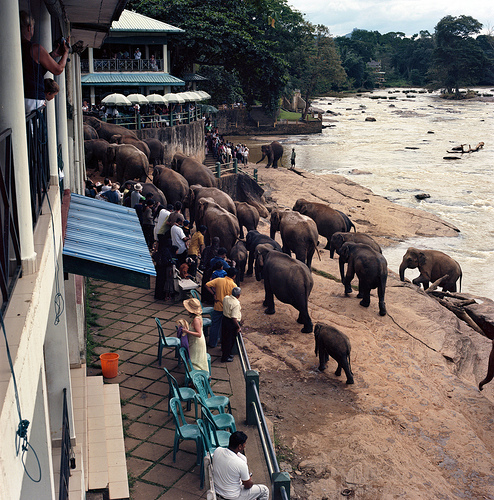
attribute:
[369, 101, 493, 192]
river — rapid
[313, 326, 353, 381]
elephant — baby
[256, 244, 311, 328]
elephant — adult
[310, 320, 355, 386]
elephant — baby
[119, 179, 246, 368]
people — gathered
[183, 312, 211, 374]
dress — long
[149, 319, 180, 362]
chair — green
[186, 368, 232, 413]
chair — green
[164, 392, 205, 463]
chair — green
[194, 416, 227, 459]
chair — green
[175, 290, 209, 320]
hat — straw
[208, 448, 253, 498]
shirt — white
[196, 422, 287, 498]
man — sitting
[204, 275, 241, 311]
shirt — yellow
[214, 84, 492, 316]
water — dark, green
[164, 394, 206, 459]
chair — blue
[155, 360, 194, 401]
chair — blue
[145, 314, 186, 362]
chair — blue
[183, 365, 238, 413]
chair — blue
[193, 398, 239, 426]
chair — blue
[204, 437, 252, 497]
shirt — white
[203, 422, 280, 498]
man — in white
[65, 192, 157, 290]
awning — blue, tin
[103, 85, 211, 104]
umbrellas — white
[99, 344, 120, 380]
bucket — orange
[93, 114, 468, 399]
elephants — Asian, herd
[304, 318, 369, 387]
elephant — small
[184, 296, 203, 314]
hat — tan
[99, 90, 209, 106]
umbrellas — white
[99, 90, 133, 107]
umbrella — white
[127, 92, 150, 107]
umbrella — white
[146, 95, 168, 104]
umbrella — white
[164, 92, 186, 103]
umbrella — white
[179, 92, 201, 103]
umbrella — white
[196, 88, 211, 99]
umbrella — white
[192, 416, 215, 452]
chair — green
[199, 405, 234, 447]
chair — green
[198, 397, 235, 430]
chair — green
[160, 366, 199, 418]
chair — green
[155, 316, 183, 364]
chair — green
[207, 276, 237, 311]
shirt — orange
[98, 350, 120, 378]
bucket — orange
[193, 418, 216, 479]
chair — blue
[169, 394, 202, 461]
chair — blue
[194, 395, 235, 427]
chair — blue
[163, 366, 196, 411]
chair — blue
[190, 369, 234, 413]
chair — blue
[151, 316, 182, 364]
chair — blue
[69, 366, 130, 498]
staircase — white, tiled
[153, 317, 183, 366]
chair — plastic, blue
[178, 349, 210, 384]
chair — plastic, blue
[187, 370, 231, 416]
chair — plastic, blue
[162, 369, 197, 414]
chair — plastic, blue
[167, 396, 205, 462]
chair — plastic, blue